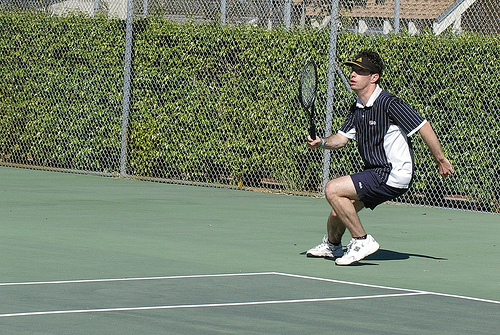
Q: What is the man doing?
A: Playing tennis.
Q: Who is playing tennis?
A: A man.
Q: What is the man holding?
A: A racket.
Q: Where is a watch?
A: Man's wrist.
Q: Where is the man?
A: Tennis court.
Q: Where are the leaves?
A: On the bushes.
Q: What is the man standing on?
A: Court.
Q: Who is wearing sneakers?
A: The man.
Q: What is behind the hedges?
A: Houses.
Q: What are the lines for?
A: Court boundaries.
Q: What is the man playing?
A: Tennis.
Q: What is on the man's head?
A: Visor.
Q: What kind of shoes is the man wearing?
A: Tennis Shoes.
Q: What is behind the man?
A: Fence.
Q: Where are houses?
A: Behind fence.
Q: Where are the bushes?
A: Behind fence.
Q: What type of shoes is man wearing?
A: Tennis shoes.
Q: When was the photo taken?
A: Daytime.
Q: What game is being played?
A: Tennis.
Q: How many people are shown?
A: One.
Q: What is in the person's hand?
A: Tennis racket.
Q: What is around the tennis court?
A: Fence.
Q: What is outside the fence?
A: Shrubs.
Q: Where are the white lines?
A: Tennis court.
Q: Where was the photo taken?
A: Tennis court.